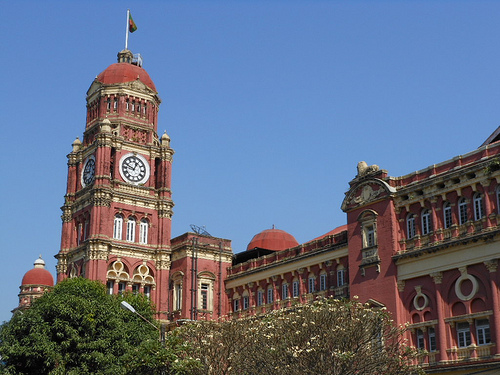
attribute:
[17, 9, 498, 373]
building — brick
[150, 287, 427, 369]
flowers — white